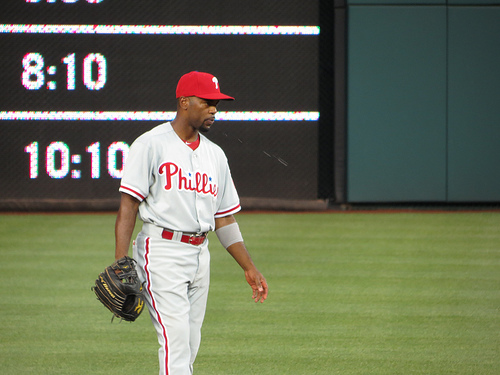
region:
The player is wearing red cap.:
[148, 63, 238, 110]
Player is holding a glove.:
[87, 250, 154, 312]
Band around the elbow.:
[213, 217, 250, 252]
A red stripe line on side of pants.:
[143, 234, 170, 371]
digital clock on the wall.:
[11, 38, 120, 190]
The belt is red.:
[158, 221, 226, 251]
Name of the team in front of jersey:
[156, 155, 231, 196]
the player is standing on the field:
[128, 85, 248, 356]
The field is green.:
[271, 212, 470, 325]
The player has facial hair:
[199, 115, 220, 133]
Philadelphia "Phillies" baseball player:
[93, 68, 270, 371]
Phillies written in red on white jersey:
[156, 161, 222, 193]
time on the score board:
[17, 48, 110, 92]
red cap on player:
[171, 69, 230, 101]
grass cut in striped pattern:
[291, 217, 492, 363]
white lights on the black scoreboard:
[6, 89, 131, 137]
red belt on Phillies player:
[148, 227, 210, 247]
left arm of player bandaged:
[215, 212, 272, 307]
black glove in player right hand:
[88, 253, 152, 325]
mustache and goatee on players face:
[197, 112, 219, 135]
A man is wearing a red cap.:
[168, 67, 249, 137]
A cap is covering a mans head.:
[156, 65, 246, 176]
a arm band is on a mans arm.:
[205, 215, 252, 264]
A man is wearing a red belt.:
[157, 220, 212, 256]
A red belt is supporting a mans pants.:
[147, 220, 225, 335]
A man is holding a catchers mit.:
[92, 249, 157, 336]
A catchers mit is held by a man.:
[63, 270, 164, 344]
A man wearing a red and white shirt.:
[111, 155, 232, 215]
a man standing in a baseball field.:
[121, 88, 201, 374]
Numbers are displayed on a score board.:
[19, 53, 114, 221]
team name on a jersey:
[160, 160, 216, 192]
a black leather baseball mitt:
[93, 265, 160, 316]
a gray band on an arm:
[214, 222, 249, 245]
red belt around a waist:
[160, 225, 210, 242]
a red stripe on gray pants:
[141, 241, 169, 373]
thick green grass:
[298, 225, 462, 366]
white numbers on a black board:
[16, 40, 123, 98]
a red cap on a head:
[169, 73, 221, 101]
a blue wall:
[354, 35, 481, 205]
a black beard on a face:
[201, 117, 208, 129]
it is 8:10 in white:
[18, 52, 105, 93]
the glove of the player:
[93, 259, 148, 319]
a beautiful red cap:
[177, 73, 232, 102]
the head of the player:
[176, 76, 221, 131]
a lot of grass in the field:
[310, 232, 482, 372]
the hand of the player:
[243, 269, 268, 304]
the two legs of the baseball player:
[136, 227, 210, 373]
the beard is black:
[198, 116, 218, 132]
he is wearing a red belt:
[163, 230, 206, 245]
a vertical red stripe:
[139, 237, 176, 373]